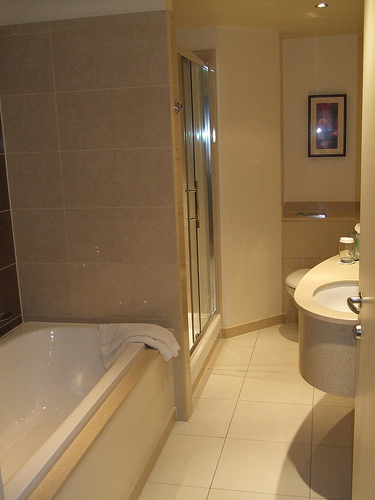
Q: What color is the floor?
A: White.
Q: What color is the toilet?
A: White.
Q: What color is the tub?
A: White.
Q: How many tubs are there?
A: One.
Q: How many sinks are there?
A: One.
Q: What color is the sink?
A: White.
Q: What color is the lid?
A: White.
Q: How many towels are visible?
A: One.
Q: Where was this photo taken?
A: A bathroom.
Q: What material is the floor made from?
A: Tile.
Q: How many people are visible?
A: Zero.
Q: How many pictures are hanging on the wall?
A: One.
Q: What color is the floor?
A: Tan.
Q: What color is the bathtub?
A: White.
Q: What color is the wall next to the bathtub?
A: Tan.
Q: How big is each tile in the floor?
A: 12 inches across.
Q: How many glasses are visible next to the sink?
A: One.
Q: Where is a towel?
A: On the tub.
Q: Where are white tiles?
A: On the floor.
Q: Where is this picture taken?
A: In the bathroom.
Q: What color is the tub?
A: White.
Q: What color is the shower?
A: Silver.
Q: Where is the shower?
A: Next to the tub.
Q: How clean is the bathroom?
A: It is very neat.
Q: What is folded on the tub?
A: A towel.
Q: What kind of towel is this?
A: Terry cloth.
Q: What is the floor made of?
A: Tile.